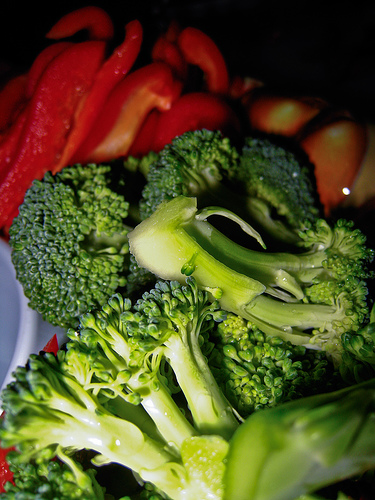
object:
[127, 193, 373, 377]
broccoli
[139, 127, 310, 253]
broccoli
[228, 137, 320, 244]
broccoli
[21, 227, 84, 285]
bulbs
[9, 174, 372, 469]
broccoli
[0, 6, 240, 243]
pepper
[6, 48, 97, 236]
pepper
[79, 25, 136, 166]
pepper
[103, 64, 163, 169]
pepper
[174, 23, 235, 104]
pepper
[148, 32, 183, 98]
pepper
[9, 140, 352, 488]
broccoli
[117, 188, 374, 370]
broccoli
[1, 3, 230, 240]
peppers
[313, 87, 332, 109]
ground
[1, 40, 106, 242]
pepper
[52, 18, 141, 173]
pepper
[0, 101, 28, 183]
pepper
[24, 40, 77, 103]
pepper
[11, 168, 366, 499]
broccoli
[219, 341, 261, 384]
floret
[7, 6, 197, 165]
pepper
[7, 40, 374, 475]
vegetables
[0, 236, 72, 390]
plate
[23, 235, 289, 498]
broccoli bunch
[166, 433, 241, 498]
area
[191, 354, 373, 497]
broccoli stem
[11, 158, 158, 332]
piece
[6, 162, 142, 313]
brocolli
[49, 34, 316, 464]
vegetables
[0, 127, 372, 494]
broccoli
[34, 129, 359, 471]
vegetables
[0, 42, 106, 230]
pepper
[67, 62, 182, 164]
pepper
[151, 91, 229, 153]
pepper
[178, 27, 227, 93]
pepper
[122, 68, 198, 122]
slice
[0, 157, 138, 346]
broccoli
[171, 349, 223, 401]
stem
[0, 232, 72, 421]
plate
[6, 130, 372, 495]
vetables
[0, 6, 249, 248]
vetables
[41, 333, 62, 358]
red pepper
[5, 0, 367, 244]
red pepper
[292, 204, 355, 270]
broccoli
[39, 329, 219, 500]
light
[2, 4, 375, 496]
vegetables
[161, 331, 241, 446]
stem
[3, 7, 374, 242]
pepper